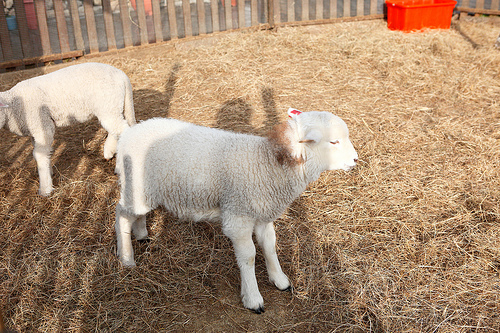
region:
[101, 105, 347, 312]
white sheep standing in pen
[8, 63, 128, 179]
white sheep standing in pen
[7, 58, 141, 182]
white sheep in pen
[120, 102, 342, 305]
white sheep in pen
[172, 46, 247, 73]
light brown hay on ground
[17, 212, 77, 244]
light brown hay on ground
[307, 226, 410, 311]
light brown hay on ground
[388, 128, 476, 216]
light brown hay on ground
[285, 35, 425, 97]
light brown hay on ground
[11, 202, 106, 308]
light brown hay on ground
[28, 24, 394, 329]
two lambs in a pen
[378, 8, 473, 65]
the bin is orange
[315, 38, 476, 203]
the straw is fresh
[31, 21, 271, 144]
the pen is wooden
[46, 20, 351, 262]
the shadow of the photographer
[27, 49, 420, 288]
the lambs are white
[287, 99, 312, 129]
the ear tag is red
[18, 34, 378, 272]
the pen is lined in straw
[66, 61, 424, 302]
this lamb has four legs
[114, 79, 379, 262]
the sheep is young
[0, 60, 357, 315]
Two lambs in the straw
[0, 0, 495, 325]
Enclosure filled with brown straw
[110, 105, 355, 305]
Lamb with a red ear tag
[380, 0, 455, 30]
Bright orange plastic container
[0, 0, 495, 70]
Wooden fence with vertical slats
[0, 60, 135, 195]
Body of a white lamb standing in the straw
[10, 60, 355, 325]
Shadows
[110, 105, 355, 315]
White lamb with tiny black hooves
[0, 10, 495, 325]
Straw covered ground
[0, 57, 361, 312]
Two young sheep with short white wool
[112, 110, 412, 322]
White sheep fenced in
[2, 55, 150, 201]
White sheep fenced in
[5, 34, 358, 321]
2 White sheep fenced in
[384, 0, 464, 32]
REd plastic container in hay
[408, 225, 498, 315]
Brown hay on ground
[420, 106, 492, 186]
Brown hay on ground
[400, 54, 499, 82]
Brown hay on ground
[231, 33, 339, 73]
Brown hay on ground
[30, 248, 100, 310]
Brown hay on ground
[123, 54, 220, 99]
Brown hay on ground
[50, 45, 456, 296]
Picture taken outdoors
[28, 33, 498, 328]
Picture taken during the day.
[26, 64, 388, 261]
Two white sheep.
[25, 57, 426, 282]
The sheep are stadnding.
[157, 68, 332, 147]
Shadows on the hay.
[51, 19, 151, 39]
A wooden fence.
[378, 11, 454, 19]
An orange tub.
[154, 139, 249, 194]
The sheep is white.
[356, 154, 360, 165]
The sheep has a black nose.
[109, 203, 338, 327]
The sheep has four legs.